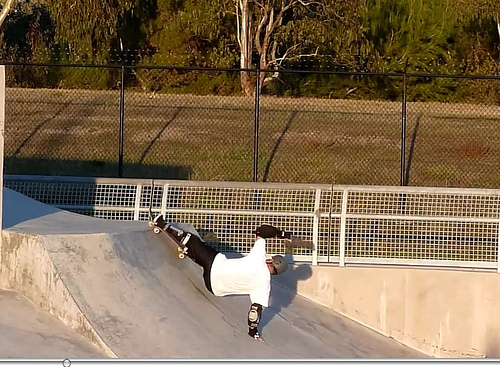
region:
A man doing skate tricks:
[142, 199, 302, 331]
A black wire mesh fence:
[122, 75, 244, 173]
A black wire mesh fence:
[260, 86, 399, 187]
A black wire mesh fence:
[419, 99, 499, 189]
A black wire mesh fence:
[11, 84, 118, 160]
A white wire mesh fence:
[342, 198, 481, 245]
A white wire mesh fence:
[77, 177, 132, 214]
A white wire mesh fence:
[200, 188, 296, 221]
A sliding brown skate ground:
[94, 280, 201, 344]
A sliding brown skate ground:
[292, 307, 370, 353]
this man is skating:
[42, 48, 384, 343]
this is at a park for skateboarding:
[30, 86, 410, 346]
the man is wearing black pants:
[155, 237, 229, 272]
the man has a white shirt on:
[212, 235, 264, 297]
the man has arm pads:
[248, 216, 328, 272]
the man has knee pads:
[157, 216, 215, 246]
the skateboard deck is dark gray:
[143, 214, 183, 246]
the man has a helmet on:
[266, 248, 306, 281]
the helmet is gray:
[272, 250, 315, 285]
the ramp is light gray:
[48, 262, 180, 349]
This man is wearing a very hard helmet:
[276, 255, 296, 291]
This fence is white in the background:
[363, 192, 404, 268]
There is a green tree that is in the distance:
[407, 43, 429, 73]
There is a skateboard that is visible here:
[151, 219, 185, 274]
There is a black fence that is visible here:
[378, 98, 440, 175]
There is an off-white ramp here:
[57, 246, 118, 308]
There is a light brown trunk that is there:
[233, 48, 264, 93]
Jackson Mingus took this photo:
[138, 58, 355, 318]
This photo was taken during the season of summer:
[118, 68, 371, 350]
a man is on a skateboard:
[146, 204, 289, 343]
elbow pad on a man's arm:
[247, 303, 261, 331]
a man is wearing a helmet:
[267, 255, 289, 275]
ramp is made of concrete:
[43, 223, 444, 365]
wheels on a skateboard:
[147, 218, 157, 233]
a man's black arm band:
[253, 222, 293, 243]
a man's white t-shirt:
[211, 236, 273, 307]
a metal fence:
[4, 171, 499, 268]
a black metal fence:
[1, 60, 499, 188]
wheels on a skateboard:
[176, 246, 186, 259]